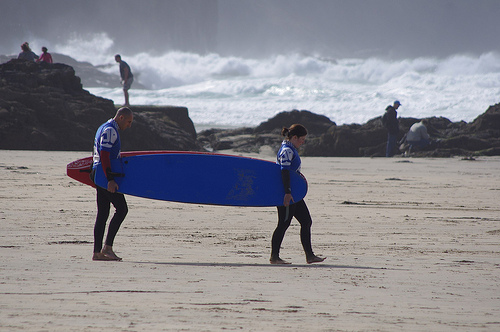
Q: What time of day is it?
A: Day time.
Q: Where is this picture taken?
A: Beach.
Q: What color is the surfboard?
A: Blue.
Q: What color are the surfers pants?
A: Black.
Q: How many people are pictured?
A: Two.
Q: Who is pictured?
A: Surfer.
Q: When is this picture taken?
A: Before surfing.